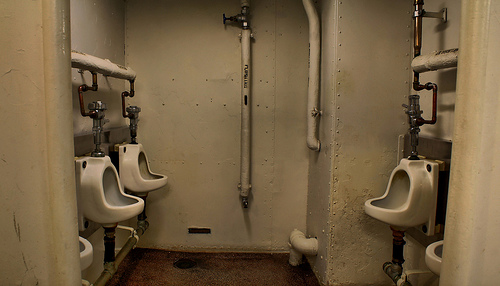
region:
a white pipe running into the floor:
[285, 227, 319, 265]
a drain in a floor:
[169, 249, 198, 272]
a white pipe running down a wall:
[299, 0, 325, 154]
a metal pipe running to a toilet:
[413, 1, 443, 133]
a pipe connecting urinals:
[88, 211, 158, 284]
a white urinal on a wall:
[361, 151, 442, 224]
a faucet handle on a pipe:
[220, 4, 253, 30]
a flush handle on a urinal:
[399, 94, 419, 119]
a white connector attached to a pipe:
[94, 220, 141, 258]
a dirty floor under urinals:
[111, 244, 323, 285]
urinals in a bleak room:
[72, 32, 438, 278]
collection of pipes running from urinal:
[72, 54, 174, 280]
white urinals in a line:
[62, 143, 176, 268]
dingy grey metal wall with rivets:
[131, 14, 306, 254]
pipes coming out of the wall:
[212, 7, 347, 280]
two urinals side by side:
[351, 137, 486, 284]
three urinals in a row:
[66, 138, 181, 275]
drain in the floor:
[167, 247, 226, 278]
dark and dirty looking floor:
[101, 217, 337, 283]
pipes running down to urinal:
[389, 1, 444, 162]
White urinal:
[364, 156, 439, 238]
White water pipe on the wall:
[238, 27, 253, 199]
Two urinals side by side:
[75, 68, 167, 226]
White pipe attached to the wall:
[301, 0, 321, 153]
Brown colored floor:
[122, 251, 302, 284]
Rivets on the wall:
[327, 1, 347, 284]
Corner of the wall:
[324, 0, 341, 284]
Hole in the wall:
[187, 227, 212, 235]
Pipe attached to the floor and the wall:
[284, 227, 320, 267]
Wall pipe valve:
[220, 10, 250, 28]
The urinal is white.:
[108, 125, 174, 210]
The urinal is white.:
[71, 143, 152, 236]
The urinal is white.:
[358, 150, 440, 240]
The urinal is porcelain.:
[111, 136, 173, 200]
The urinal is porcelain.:
[73, 148, 150, 233]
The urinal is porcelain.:
[356, 150, 448, 244]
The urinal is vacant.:
[115, 131, 176, 201]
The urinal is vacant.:
[69, 145, 151, 235]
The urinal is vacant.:
[351, 145, 441, 241]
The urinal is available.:
[352, 142, 444, 239]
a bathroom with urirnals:
[19, 2, 480, 284]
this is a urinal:
[346, 125, 440, 245]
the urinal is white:
[363, 144, 440, 253]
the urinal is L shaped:
[82, 135, 152, 236]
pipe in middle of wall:
[213, 0, 281, 237]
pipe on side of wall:
[285, 5, 350, 172]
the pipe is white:
[283, 1, 352, 208]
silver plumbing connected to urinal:
[399, 85, 429, 157]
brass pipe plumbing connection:
[399, 13, 442, 133]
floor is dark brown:
[120, 232, 327, 284]